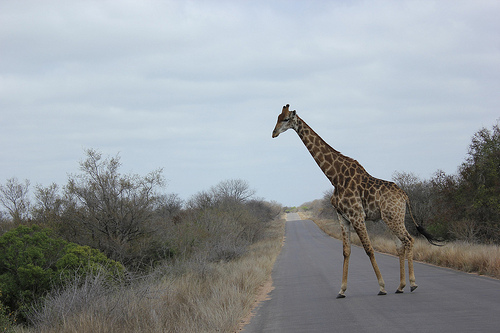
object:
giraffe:
[272, 104, 420, 300]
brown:
[333, 160, 343, 173]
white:
[284, 122, 288, 128]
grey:
[285, 264, 325, 310]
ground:
[270, 300, 491, 327]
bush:
[4, 220, 125, 321]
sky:
[53, 13, 459, 86]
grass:
[415, 237, 497, 272]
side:
[409, 247, 498, 276]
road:
[288, 220, 496, 328]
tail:
[403, 191, 458, 247]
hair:
[419, 226, 451, 247]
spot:
[349, 197, 357, 205]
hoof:
[335, 291, 350, 300]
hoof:
[377, 290, 387, 297]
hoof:
[395, 282, 407, 293]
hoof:
[410, 284, 419, 293]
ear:
[292, 110, 296, 116]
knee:
[341, 250, 352, 259]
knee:
[364, 245, 376, 258]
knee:
[395, 239, 406, 254]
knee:
[403, 236, 416, 248]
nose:
[272, 125, 277, 134]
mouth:
[272, 129, 281, 138]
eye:
[284, 118, 289, 121]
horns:
[282, 104, 290, 113]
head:
[271, 103, 295, 139]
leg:
[335, 202, 351, 300]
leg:
[382, 205, 418, 293]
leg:
[391, 219, 406, 294]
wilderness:
[45, 150, 322, 325]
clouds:
[47, 12, 191, 112]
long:
[283, 195, 335, 332]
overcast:
[68, 3, 253, 93]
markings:
[333, 159, 343, 173]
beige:
[387, 202, 395, 208]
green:
[5, 225, 76, 278]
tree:
[74, 146, 166, 259]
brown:
[453, 243, 496, 269]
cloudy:
[69, 31, 214, 105]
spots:
[324, 153, 333, 165]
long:
[298, 109, 357, 188]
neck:
[297, 111, 355, 192]